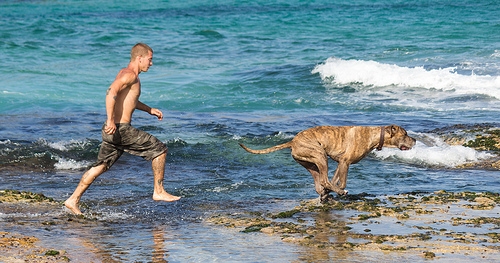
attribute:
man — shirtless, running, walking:
[61, 41, 173, 214]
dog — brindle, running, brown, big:
[245, 115, 416, 192]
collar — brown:
[378, 125, 389, 154]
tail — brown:
[240, 138, 294, 156]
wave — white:
[313, 60, 497, 108]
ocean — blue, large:
[0, 3, 497, 211]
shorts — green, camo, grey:
[90, 125, 164, 164]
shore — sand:
[4, 176, 496, 262]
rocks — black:
[7, 137, 103, 168]